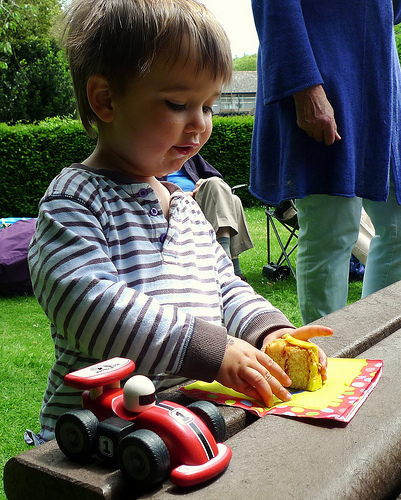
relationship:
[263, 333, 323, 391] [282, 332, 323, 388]
cake with frosting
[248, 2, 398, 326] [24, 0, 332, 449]
adult standing next to child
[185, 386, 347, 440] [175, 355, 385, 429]
polka dots on outside of napkin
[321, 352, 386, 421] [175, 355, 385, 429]
polka dots on outside of napkin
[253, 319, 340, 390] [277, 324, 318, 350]
cake with frosting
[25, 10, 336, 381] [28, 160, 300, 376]
boy wearing a shirt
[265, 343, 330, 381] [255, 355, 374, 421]
cake on a napkin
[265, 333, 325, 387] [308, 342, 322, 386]
cake with frosting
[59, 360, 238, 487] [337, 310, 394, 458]
car on bench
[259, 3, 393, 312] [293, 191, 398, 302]
person wearing pants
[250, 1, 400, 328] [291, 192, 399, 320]
person wearing blue jeans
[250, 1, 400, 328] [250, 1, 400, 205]
person wearing shirt